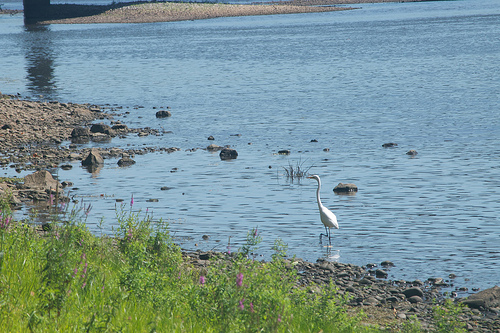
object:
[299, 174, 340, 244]
bird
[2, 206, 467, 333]
grass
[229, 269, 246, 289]
flower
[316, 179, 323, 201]
neck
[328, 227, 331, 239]
leg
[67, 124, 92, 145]
rocks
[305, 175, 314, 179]
beak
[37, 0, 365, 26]
ground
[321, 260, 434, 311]
shore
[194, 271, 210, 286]
flowers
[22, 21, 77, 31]
beam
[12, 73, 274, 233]
shoreline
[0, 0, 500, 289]
river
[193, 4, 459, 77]
background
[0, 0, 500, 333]
scene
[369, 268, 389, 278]
rock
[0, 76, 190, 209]
beach